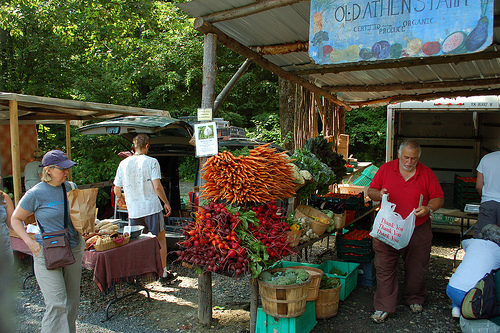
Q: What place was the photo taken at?
A: It was taken at the market.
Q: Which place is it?
A: It is a market.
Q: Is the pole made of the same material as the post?
A: Yes, both the pole and the post are made of wood.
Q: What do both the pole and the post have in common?
A: The material, both the pole and the post are wooden.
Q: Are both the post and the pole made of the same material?
A: Yes, both the post and the pole are made of wood.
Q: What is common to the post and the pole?
A: The material, both the post and the pole are wooden.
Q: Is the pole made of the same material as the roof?
A: No, the pole is made of wood and the roof is made of metal.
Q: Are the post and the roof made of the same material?
A: No, the post is made of wood and the roof is made of metal.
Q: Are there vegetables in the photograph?
A: Yes, there are vegetables.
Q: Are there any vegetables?
A: Yes, there are vegetables.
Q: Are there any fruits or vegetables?
A: Yes, there are vegetables.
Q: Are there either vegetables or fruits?
A: Yes, there are vegetables.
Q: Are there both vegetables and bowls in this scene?
A: No, there are vegetables but no bowls.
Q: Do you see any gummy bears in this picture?
A: No, there are no gummy bears.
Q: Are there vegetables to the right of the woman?
A: Yes, there are vegetables to the right of the woman.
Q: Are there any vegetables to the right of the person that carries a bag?
A: Yes, there are vegetables to the right of the woman.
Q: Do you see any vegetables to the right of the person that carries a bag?
A: Yes, there are vegetables to the right of the woman.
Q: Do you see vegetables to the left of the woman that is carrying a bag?
A: No, the vegetables are to the right of the woman.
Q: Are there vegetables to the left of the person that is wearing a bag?
A: No, the vegetables are to the right of the woman.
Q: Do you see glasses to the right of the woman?
A: No, there are vegetables to the right of the woman.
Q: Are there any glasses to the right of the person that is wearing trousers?
A: No, there are vegetables to the right of the woman.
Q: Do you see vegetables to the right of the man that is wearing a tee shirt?
A: Yes, there are vegetables to the right of the man.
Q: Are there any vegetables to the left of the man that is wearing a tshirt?
A: No, the vegetables are to the right of the man.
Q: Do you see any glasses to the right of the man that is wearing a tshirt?
A: No, there are vegetables to the right of the man.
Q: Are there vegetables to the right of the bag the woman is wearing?
A: Yes, there are vegetables to the right of the bag.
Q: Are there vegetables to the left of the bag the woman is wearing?
A: No, the vegetables are to the right of the bag.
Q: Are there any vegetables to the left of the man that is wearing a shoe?
A: Yes, there are vegetables to the left of the man.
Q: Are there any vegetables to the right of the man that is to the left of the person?
A: No, the vegetables are to the left of the man.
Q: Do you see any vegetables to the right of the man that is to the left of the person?
A: No, the vegetables are to the left of the man.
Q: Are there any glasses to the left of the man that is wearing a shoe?
A: No, there are vegetables to the left of the man.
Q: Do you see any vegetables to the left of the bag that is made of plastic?
A: Yes, there are vegetables to the left of the bag.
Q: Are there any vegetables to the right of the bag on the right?
A: No, the vegetables are to the left of the bag.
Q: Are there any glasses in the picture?
A: No, there are no glasses.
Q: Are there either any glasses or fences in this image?
A: No, there are no glasses or fences.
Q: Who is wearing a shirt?
A: The man is wearing a shirt.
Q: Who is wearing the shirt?
A: The man is wearing a shirt.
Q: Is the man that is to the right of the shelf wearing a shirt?
A: Yes, the man is wearing a shirt.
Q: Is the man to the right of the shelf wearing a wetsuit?
A: No, the man is wearing a shirt.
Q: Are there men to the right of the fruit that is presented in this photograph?
A: Yes, there is a man to the right of the fruit.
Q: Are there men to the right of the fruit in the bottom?
A: Yes, there is a man to the right of the fruit.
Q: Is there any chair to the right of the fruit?
A: No, there is a man to the right of the fruit.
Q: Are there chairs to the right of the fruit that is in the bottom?
A: No, there is a man to the right of the fruit.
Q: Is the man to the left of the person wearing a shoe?
A: Yes, the man is wearing a shoe.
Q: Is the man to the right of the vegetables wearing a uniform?
A: No, the man is wearing a shoe.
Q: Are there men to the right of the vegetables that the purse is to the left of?
A: Yes, there is a man to the right of the vegetables.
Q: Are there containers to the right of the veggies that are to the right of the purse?
A: No, there is a man to the right of the vegetables.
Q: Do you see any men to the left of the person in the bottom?
A: Yes, there is a man to the left of the person.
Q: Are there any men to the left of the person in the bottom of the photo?
A: Yes, there is a man to the left of the person.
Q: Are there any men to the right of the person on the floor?
A: No, the man is to the left of the person.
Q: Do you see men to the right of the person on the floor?
A: No, the man is to the left of the person.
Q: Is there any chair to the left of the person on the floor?
A: No, there is a man to the left of the person.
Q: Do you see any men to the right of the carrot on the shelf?
A: Yes, there is a man to the right of the carrot.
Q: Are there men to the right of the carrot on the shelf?
A: Yes, there is a man to the right of the carrot.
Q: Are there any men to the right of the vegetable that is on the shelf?
A: Yes, there is a man to the right of the carrot.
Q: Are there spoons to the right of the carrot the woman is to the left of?
A: No, there is a man to the right of the carrot.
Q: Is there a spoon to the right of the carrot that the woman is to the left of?
A: No, there is a man to the right of the carrot.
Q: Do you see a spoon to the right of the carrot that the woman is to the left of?
A: No, there is a man to the right of the carrot.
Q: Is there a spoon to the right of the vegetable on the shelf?
A: No, there is a man to the right of the carrot.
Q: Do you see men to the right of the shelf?
A: Yes, there is a man to the right of the shelf.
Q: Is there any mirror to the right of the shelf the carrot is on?
A: No, there is a man to the right of the shelf.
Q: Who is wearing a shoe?
A: The man is wearing a shoe.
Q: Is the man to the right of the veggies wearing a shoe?
A: Yes, the man is wearing a shoe.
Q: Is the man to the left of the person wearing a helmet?
A: No, the man is wearing a shoe.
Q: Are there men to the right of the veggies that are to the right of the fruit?
A: Yes, there is a man to the right of the veggies.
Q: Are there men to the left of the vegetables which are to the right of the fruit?
A: No, the man is to the right of the veggies.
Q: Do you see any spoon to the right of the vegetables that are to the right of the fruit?
A: No, there is a man to the right of the vegetables.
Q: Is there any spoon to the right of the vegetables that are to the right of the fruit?
A: No, there is a man to the right of the vegetables.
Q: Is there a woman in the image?
A: Yes, there is a woman.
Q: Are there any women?
A: Yes, there is a woman.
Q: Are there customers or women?
A: Yes, there is a woman.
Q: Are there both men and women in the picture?
A: Yes, there are both a woman and a man.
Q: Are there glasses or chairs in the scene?
A: No, there are no glasses or chairs.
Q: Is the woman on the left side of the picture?
A: Yes, the woman is on the left of the image.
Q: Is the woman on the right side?
A: No, the woman is on the left of the image.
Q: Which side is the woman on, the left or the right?
A: The woman is on the left of the image.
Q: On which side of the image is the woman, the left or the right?
A: The woman is on the left of the image.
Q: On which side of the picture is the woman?
A: The woman is on the left of the image.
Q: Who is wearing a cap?
A: The woman is wearing a cap.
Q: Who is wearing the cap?
A: The woman is wearing a cap.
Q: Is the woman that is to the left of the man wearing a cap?
A: Yes, the woman is wearing a cap.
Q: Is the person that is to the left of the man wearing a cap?
A: Yes, the woman is wearing a cap.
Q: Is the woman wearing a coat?
A: No, the woman is wearing a cap.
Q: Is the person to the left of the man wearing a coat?
A: No, the woman is wearing a cap.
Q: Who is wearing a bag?
A: The woman is wearing a bag.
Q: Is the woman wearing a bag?
A: Yes, the woman is wearing a bag.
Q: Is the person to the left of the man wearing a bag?
A: Yes, the woman is wearing a bag.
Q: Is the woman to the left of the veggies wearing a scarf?
A: No, the woman is wearing a bag.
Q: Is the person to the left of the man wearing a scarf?
A: No, the woman is wearing a bag.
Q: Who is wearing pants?
A: The woman is wearing pants.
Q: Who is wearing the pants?
A: The woman is wearing pants.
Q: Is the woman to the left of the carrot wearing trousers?
A: Yes, the woman is wearing trousers.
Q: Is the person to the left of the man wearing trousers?
A: Yes, the woman is wearing trousers.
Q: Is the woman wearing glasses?
A: No, the woman is wearing trousers.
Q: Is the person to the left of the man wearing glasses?
A: No, the woman is wearing trousers.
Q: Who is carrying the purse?
A: The woman is carrying the purse.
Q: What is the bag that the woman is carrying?
A: The bag is a purse.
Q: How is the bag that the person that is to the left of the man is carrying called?
A: The bag is a purse.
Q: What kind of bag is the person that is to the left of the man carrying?
A: The woman is carrying a purse.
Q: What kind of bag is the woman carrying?
A: The woman is carrying a purse.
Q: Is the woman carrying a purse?
A: Yes, the woman is carrying a purse.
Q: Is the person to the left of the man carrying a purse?
A: Yes, the woman is carrying a purse.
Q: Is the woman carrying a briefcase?
A: No, the woman is carrying a purse.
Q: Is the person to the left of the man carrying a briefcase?
A: No, the woman is carrying a purse.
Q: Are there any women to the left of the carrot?
A: Yes, there is a woman to the left of the carrot.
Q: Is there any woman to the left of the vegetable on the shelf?
A: Yes, there is a woman to the left of the carrot.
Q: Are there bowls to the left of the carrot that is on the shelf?
A: No, there is a woman to the left of the carrot.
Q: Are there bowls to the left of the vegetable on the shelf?
A: No, there is a woman to the left of the carrot.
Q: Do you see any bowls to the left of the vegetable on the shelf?
A: No, there is a woman to the left of the carrot.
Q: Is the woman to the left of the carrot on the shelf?
A: Yes, the woman is to the left of the carrot.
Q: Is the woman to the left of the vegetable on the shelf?
A: Yes, the woman is to the left of the carrot.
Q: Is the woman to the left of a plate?
A: No, the woman is to the left of the carrot.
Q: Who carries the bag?
A: The woman carries the bag.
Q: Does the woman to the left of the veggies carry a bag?
A: Yes, the woman carries a bag.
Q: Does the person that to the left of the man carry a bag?
A: Yes, the woman carries a bag.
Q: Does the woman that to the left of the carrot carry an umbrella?
A: No, the woman carries a bag.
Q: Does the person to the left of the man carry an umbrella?
A: No, the woman carries a bag.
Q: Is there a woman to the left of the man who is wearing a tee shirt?
A: Yes, there is a woman to the left of the man.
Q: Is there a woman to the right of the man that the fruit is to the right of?
A: No, the woman is to the left of the man.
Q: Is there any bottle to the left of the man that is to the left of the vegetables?
A: No, there is a woman to the left of the man.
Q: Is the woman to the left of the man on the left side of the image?
A: Yes, the woman is to the left of the man.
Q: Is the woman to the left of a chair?
A: No, the woman is to the left of the man.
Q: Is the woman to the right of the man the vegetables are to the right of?
A: No, the woman is to the left of the man.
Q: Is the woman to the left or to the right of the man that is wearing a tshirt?
A: The woman is to the left of the man.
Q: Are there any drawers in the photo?
A: No, there are no drawers.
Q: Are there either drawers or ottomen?
A: No, there are no drawers or ottomen.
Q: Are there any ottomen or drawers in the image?
A: No, there are no drawers or ottomen.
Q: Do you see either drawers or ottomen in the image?
A: No, there are no drawers or ottomen.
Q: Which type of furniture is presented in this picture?
A: The furniture is a shelf.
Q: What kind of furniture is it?
A: The piece of furniture is a shelf.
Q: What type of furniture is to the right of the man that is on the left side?
A: The piece of furniture is a shelf.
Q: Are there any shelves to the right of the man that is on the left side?
A: Yes, there is a shelf to the right of the man.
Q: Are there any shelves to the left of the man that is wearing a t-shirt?
A: No, the shelf is to the right of the man.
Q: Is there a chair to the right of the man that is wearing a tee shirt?
A: No, there is a shelf to the right of the man.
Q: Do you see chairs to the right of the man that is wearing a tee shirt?
A: No, there is a shelf to the right of the man.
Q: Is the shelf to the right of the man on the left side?
A: Yes, the shelf is to the right of the man.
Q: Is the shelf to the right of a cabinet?
A: No, the shelf is to the right of the man.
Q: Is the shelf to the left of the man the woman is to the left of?
A: No, the shelf is to the right of the man.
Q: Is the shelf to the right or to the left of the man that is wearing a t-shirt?
A: The shelf is to the right of the man.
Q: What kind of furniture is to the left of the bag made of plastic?
A: The piece of furniture is a shelf.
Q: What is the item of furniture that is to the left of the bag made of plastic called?
A: The piece of furniture is a shelf.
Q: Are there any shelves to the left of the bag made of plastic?
A: Yes, there is a shelf to the left of the bag.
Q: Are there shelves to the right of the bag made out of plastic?
A: No, the shelf is to the left of the bag.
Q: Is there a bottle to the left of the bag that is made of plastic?
A: No, there is a shelf to the left of the bag.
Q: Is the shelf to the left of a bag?
A: Yes, the shelf is to the left of a bag.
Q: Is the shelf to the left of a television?
A: No, the shelf is to the left of a bag.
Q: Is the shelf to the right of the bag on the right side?
A: No, the shelf is to the left of the bag.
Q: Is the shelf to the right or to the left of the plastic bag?
A: The shelf is to the left of the bag.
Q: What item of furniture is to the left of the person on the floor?
A: The piece of furniture is a shelf.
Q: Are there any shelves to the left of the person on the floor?
A: Yes, there is a shelf to the left of the person.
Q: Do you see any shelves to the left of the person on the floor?
A: Yes, there is a shelf to the left of the person.